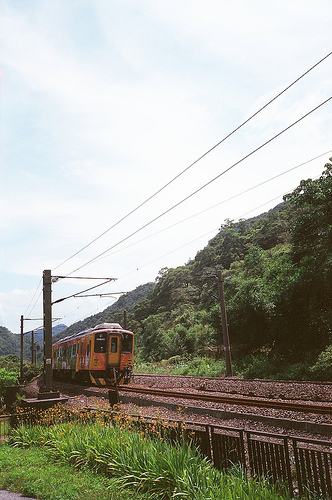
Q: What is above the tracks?
A: Wires.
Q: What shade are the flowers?
A: Orange.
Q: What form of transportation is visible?
A: Train.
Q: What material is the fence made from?
A: Metal.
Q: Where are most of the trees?
A: Right of the train.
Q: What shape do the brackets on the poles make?
A: Triangle.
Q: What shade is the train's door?
A: Yellow.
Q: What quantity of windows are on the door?
A: 1.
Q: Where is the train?
A: Tracks.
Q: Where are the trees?
A: Background by the train.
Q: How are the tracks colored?
A: Brown and rusty.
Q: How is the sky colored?
A: Blue.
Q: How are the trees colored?
A: Green.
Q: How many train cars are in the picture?
A: One.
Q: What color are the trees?
A: Green.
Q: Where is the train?
A: On the tracks.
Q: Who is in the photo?
A: No one.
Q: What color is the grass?
A: Green.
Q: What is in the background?
A: Mountains.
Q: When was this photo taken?
A: During the day.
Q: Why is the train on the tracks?
A: To get the train to the station.